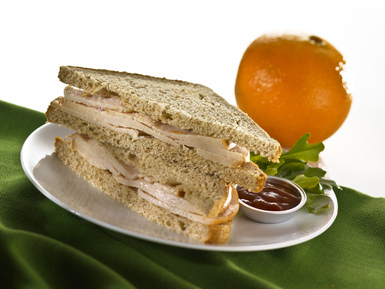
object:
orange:
[234, 34, 352, 150]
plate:
[20, 122, 339, 251]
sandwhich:
[46, 65, 283, 244]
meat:
[51, 86, 250, 168]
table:
[0, 98, 385, 288]